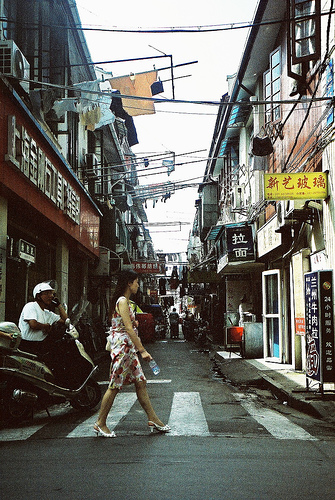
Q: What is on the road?
A: Lines.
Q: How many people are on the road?
A: 2.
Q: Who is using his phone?
A: The man at the back.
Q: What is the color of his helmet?
A: White.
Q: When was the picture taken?
A: During the day.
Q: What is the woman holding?
A: Bottle.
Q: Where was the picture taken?
A: On a city street.